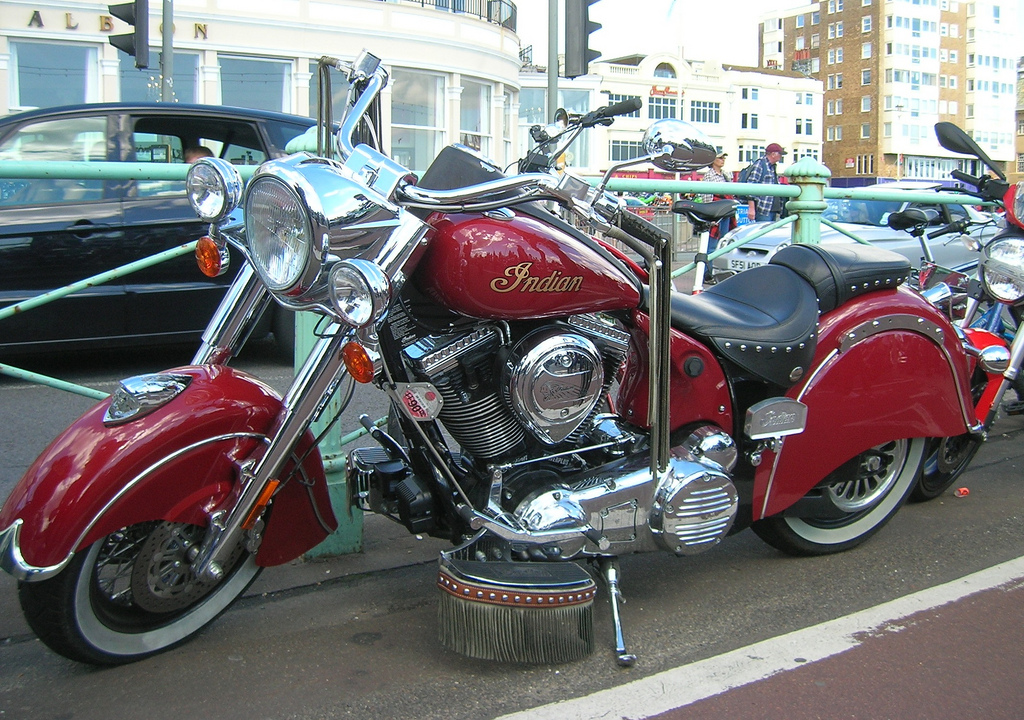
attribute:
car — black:
[1, 97, 349, 366]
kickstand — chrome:
[604, 549, 641, 670]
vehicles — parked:
[5, 90, 301, 372]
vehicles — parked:
[711, 176, 992, 280]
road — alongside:
[270, 589, 977, 715]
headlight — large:
[244, 169, 316, 297]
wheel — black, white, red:
[13, 369, 348, 674]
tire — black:
[9, 458, 288, 677]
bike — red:
[2, 52, 1003, 688]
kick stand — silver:
[583, 547, 644, 664]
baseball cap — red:
[758, 137, 787, 150]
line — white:
[680, 642, 776, 705]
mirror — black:
[933, 111, 990, 179]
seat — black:
[678, 262, 836, 396]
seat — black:
[691, 269, 795, 352]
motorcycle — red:
[99, 102, 977, 614]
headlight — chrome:
[231, 169, 324, 297]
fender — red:
[34, 402, 277, 519]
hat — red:
[762, 135, 789, 157]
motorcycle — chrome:
[183, 106, 972, 655]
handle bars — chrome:
[332, 65, 598, 217]